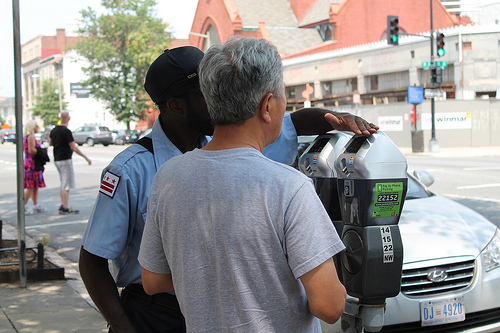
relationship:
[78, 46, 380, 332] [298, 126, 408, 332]
people touching meter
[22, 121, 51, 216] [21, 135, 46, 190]
woman in a dress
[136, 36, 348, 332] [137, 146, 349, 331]
man wearing shirt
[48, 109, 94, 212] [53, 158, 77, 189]
man in shorts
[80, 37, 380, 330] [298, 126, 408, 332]
people looking at meter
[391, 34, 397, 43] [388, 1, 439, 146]
light on pole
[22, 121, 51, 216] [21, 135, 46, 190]
woman wearing dress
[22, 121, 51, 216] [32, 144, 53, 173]
woman carrying sweater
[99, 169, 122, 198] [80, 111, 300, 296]
patch on shirt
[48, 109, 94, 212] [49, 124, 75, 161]
man wearing shirt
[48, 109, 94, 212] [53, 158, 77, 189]
man wearing shorts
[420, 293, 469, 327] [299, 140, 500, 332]
license plate in front of car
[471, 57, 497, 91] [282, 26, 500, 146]
sign on side of wall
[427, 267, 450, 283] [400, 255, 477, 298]
insignia on grill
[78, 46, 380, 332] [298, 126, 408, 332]
people shading meter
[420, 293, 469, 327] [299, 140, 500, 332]
license plate on parked car